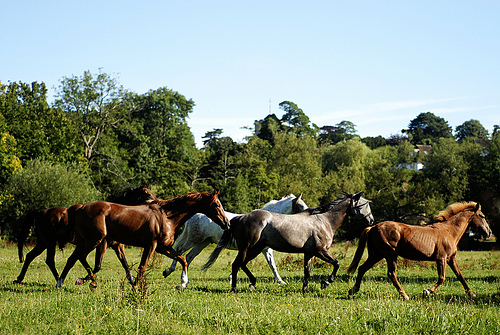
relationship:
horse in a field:
[344, 200, 493, 305] [3, 227, 497, 334]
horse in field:
[344, 200, 493, 305] [3, 227, 497, 334]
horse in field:
[54, 187, 232, 301] [3, 227, 497, 334]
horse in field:
[162, 191, 310, 294] [3, 227, 497, 334]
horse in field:
[202, 188, 376, 299] [3, 227, 497, 334]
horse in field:
[13, 184, 160, 294] [3, 227, 497, 334]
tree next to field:
[397, 175, 447, 223] [3, 227, 497, 334]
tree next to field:
[274, 150, 324, 214] [3, 227, 497, 334]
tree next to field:
[215, 169, 253, 216] [3, 227, 497, 334]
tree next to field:
[8, 157, 105, 265] [3, 227, 497, 334]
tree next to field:
[1, 130, 27, 204] [3, 227, 497, 334]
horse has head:
[344, 200, 493, 305] [468, 201, 495, 240]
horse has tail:
[344, 200, 493, 305] [345, 226, 374, 279]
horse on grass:
[202, 188, 376, 299] [4, 245, 500, 334]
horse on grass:
[344, 200, 493, 305] [4, 245, 500, 334]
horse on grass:
[13, 184, 160, 294] [4, 245, 500, 334]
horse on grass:
[54, 187, 232, 301] [4, 245, 500, 334]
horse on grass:
[162, 191, 310, 294] [4, 245, 500, 334]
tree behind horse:
[397, 175, 447, 223] [344, 200, 493, 305]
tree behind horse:
[274, 150, 324, 214] [202, 188, 376, 299]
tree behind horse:
[215, 169, 253, 216] [162, 191, 310, 294]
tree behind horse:
[8, 157, 105, 265] [13, 184, 160, 294]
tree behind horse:
[1, 130, 27, 204] [13, 184, 160, 294]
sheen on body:
[253, 209, 316, 248] [242, 208, 336, 259]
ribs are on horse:
[405, 228, 437, 259] [344, 200, 493, 305]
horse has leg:
[54, 187, 232, 301] [163, 248, 190, 293]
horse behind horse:
[162, 191, 310, 294] [54, 187, 232, 301]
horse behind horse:
[162, 191, 310, 294] [202, 188, 376, 299]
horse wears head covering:
[202, 188, 376, 299] [351, 193, 377, 226]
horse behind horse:
[13, 184, 160, 294] [54, 187, 232, 301]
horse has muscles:
[54, 187, 232, 301] [152, 209, 178, 250]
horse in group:
[344, 200, 493, 305] [7, 181, 493, 305]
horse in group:
[202, 188, 376, 299] [7, 181, 493, 305]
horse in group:
[54, 187, 232, 301] [7, 181, 493, 305]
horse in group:
[13, 184, 160, 294] [7, 181, 493, 305]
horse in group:
[162, 191, 310, 294] [7, 181, 493, 305]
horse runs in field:
[344, 200, 493, 305] [3, 227, 497, 334]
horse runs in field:
[202, 188, 376, 299] [3, 227, 497, 334]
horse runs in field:
[162, 191, 310, 294] [3, 227, 497, 334]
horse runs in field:
[54, 187, 232, 301] [3, 227, 497, 334]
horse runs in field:
[13, 184, 160, 294] [3, 227, 497, 334]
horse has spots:
[162, 191, 310, 294] [187, 216, 204, 245]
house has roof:
[389, 143, 435, 171] [415, 142, 434, 154]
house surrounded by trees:
[389, 143, 435, 171] [228, 97, 500, 244]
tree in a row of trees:
[397, 175, 447, 223] [1, 67, 500, 243]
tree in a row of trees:
[274, 150, 324, 214] [1, 67, 500, 243]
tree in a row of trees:
[215, 169, 253, 216] [1, 67, 500, 243]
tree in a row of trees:
[8, 157, 105, 265] [1, 67, 500, 243]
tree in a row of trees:
[1, 130, 27, 204] [1, 67, 500, 243]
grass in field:
[4, 245, 500, 334] [3, 227, 497, 334]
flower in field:
[103, 304, 116, 314] [3, 227, 497, 334]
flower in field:
[277, 300, 297, 311] [3, 227, 497, 334]